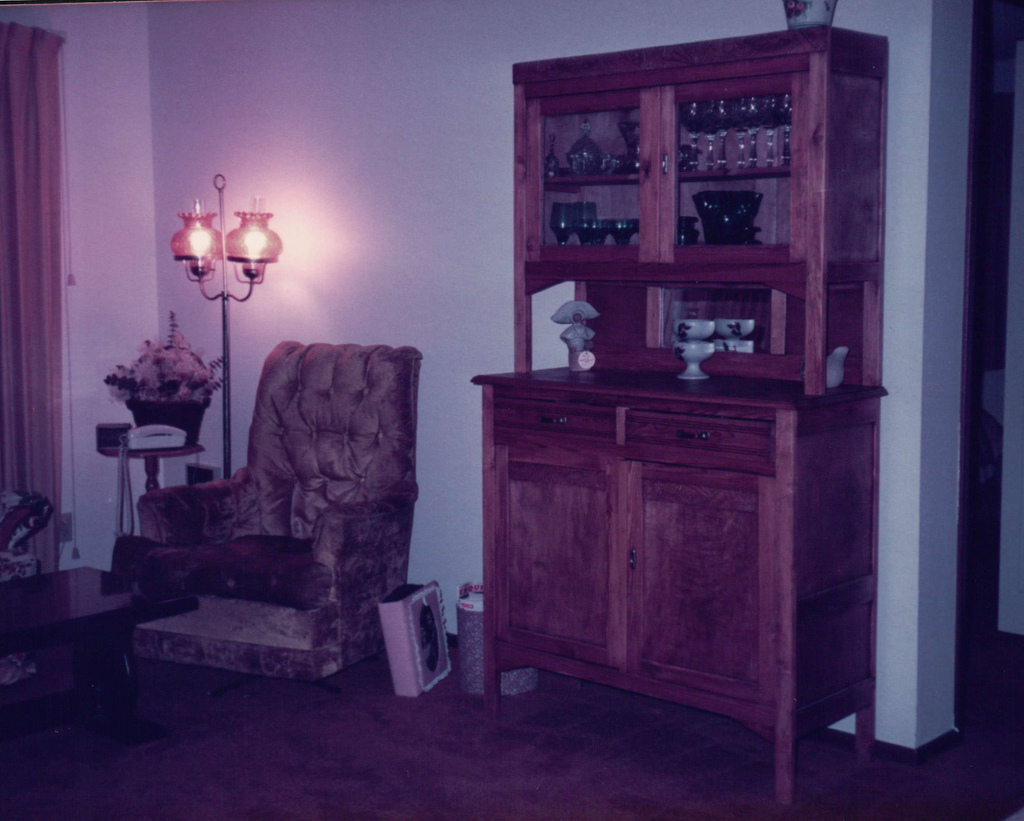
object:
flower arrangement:
[106, 325, 226, 448]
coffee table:
[0, 547, 205, 761]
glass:
[589, 216, 614, 249]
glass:
[760, 90, 781, 168]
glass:
[735, 223, 764, 248]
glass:
[617, 117, 644, 175]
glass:
[548, 191, 578, 247]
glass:
[542, 119, 566, 178]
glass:
[710, 93, 730, 173]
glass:
[739, 95, 765, 167]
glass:
[568, 152, 595, 177]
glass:
[572, 196, 599, 249]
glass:
[775, 90, 797, 167]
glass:
[699, 98, 722, 167]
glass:
[691, 187, 764, 244]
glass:
[676, 99, 705, 175]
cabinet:
[527, 100, 661, 257]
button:
[315, 473, 337, 491]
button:
[370, 427, 389, 443]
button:
[342, 428, 360, 446]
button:
[360, 384, 373, 402]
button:
[291, 380, 309, 393]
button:
[351, 473, 371, 487]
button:
[276, 422, 299, 438]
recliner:
[131, 403, 430, 619]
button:
[307, 425, 324, 445]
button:
[324, 384, 336, 401]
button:
[286, 471, 302, 485]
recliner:
[248, 333, 420, 518]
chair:
[130, 339, 422, 683]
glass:
[563, 113, 607, 178]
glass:
[673, 213, 702, 250]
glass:
[609, 215, 640, 247]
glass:
[729, 94, 751, 169]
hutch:
[534, 82, 805, 263]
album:
[378, 579, 452, 698]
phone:
[124, 424, 187, 453]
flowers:
[102, 361, 145, 392]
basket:
[102, 311, 233, 446]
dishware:
[666, 314, 722, 343]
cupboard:
[472, 32, 887, 790]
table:
[97, 419, 210, 564]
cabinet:
[648, 56, 823, 272]